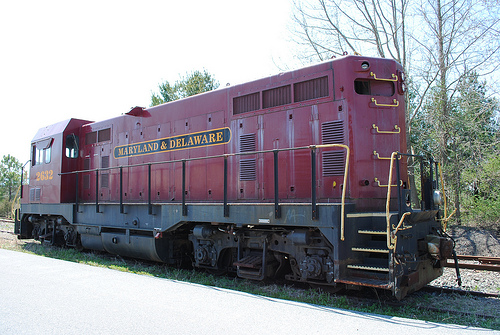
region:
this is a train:
[26, 62, 418, 235]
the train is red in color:
[28, 42, 427, 199]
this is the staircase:
[358, 228, 388, 268]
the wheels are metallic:
[228, 233, 320, 274]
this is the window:
[64, 140, 79, 157]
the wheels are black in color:
[300, 244, 316, 249]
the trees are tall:
[328, 11, 443, 46]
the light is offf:
[360, 60, 375, 70]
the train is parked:
[17, 56, 412, 226]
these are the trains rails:
[449, 253, 494, 325]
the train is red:
[26, 50, 440, 305]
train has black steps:
[348, 205, 411, 302]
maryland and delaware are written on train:
[111, 127, 241, 156]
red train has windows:
[32, 144, 62, 168]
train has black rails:
[69, 149, 366, 218]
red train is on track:
[446, 248, 498, 324]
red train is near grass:
[31, 250, 478, 334]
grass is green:
[11, 232, 490, 332]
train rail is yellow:
[317, 140, 399, 252]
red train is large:
[21, 55, 486, 307]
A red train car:
[29, 66, 447, 307]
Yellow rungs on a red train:
[360, 63, 416, 202]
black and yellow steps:
[321, 202, 410, 298]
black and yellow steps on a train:
[336, 197, 428, 321]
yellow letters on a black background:
[105, 132, 246, 161]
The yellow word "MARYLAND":
[109, 137, 160, 159]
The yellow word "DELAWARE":
[166, 128, 238, 152]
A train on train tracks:
[114, 79, 498, 296]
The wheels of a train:
[17, 215, 329, 285]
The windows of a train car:
[16, 131, 76, 182]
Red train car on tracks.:
[88, 122, 340, 242]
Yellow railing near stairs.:
[372, 152, 396, 264]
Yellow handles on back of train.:
[362, 63, 404, 215]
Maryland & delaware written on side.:
[112, 146, 267, 176]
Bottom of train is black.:
[101, 210, 327, 285]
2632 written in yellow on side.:
[30, 165, 91, 190]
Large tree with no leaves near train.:
[341, 18, 482, 126]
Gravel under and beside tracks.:
[144, 230, 466, 323]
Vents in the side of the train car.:
[229, 85, 346, 138]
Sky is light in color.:
[21, 20, 146, 80]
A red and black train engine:
[6, 35, 479, 310]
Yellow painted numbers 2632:
[26, 168, 58, 185]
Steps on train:
[342, 191, 418, 291]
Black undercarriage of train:
[16, 200, 343, 280]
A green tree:
[1, 155, 20, 220]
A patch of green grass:
[35, 242, 92, 261]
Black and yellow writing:
[104, 132, 235, 159]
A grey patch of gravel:
[470, 270, 499, 290]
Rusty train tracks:
[461, 246, 499, 275]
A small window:
[62, 132, 82, 159]